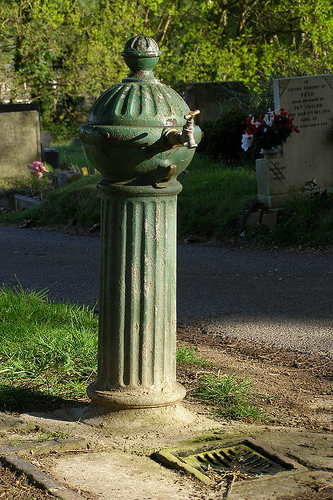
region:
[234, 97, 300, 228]
a grave with flowers.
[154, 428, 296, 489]
A dirty drain.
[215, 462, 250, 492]
A brown stick with leaves.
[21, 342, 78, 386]
Green grass and dirt.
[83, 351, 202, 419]
A green stone pillar.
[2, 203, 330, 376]
A gravel walkway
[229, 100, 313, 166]
Red and white flowers.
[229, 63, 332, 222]
A grave with some flowers.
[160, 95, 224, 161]
A gray faucet with a brown handle.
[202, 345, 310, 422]
Brown dirt and some weeds.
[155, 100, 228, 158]
This is a faucet.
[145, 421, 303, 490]
This is a drain.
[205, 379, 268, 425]
This is grass.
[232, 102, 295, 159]
These are flowers.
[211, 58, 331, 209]
This is a grave.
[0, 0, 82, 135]
This is a tree.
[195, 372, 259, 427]
Green grass on the ground.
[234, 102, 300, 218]
This is a grave with flowers.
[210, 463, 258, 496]
This is a stick.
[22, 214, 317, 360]
This is a pathway.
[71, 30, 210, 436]
Green fire hydrant on side of road.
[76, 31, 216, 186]
Top of fire hydrant.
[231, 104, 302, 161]
Red and white flowers in vase.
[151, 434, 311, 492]
Drain in ground next to fire hydrant.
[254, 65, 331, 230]
Head stone inside cemetery.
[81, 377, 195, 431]
Base of fire hydrant.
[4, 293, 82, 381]
Grass growing in cemetery.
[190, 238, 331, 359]
A road inside cemetery.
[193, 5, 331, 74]
Trees growing behind cemetery.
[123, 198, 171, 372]
Rust growing on side of fire hydrant.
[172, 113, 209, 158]
the faucet is gray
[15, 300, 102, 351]
the grass is green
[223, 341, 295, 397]
the ground is brown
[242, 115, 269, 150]
the flowers are red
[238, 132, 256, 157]
the flowers are white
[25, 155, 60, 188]
the flowers are pink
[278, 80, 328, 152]
the epitaph is gray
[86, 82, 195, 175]
the fire hydrant is green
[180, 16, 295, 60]
the bushes is green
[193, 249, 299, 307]
the ground is gray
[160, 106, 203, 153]
Water spout on monument.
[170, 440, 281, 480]
Water drainage rectangle below water spout.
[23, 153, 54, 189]
Pink and white flowers.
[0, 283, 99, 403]
Large patch of green grass next to monument with water faucet on it.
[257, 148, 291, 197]
Stone vase holder holding red and white flowers.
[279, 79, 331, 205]
Tombstone next to the red and white flowers in stone vase.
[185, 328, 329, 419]
Patch of dirt above the water drain on the ground.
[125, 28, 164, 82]
Round structure top on green monument with water spout.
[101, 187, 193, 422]
Lower post structure of monument with water spout.